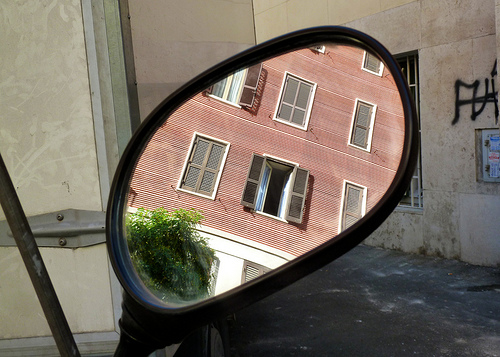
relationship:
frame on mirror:
[105, 23, 420, 315] [115, 23, 417, 304]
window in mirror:
[256, 155, 298, 221] [115, 23, 417, 304]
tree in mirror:
[130, 208, 214, 303] [115, 23, 417, 304]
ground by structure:
[226, 240, 499, 356] [128, 2, 499, 268]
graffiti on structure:
[452, 59, 500, 128] [128, 2, 499, 268]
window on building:
[256, 155, 298, 221] [123, 43, 405, 294]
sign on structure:
[480, 127, 499, 184] [128, 2, 499, 268]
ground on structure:
[226, 240, 499, 356] [128, 2, 499, 268]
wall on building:
[257, 6, 491, 256] [1, 2, 495, 351]